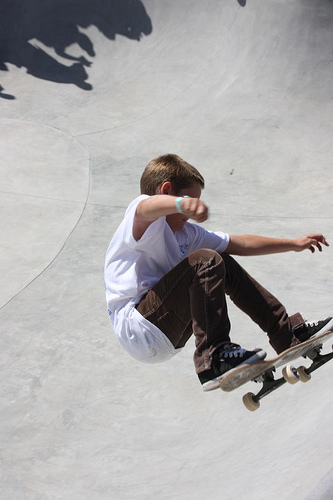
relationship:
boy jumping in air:
[89, 143, 332, 397] [74, 131, 322, 417]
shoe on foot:
[194, 336, 268, 403] [197, 331, 236, 380]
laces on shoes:
[218, 342, 249, 360] [217, 330, 331, 411]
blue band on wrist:
[169, 192, 194, 223] [283, 230, 305, 257]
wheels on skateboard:
[240, 345, 332, 411] [221, 329, 331, 411]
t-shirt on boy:
[101, 203, 198, 319] [94, 139, 244, 315]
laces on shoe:
[218, 342, 249, 360] [188, 341, 268, 394]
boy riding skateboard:
[104, 153, 331, 395] [221, 329, 331, 411]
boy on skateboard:
[104, 153, 331, 395] [195, 319, 331, 413]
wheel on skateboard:
[245, 392, 258, 410] [184, 328, 317, 411]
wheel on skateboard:
[291, 366, 313, 386] [231, 329, 328, 388]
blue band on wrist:
[175, 192, 188, 217] [166, 193, 192, 218]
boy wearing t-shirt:
[104, 153, 331, 395] [98, 193, 228, 365]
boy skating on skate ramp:
[104, 153, 331, 395] [4, 5, 323, 491]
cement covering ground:
[60, 396, 255, 485] [5, 349, 324, 495]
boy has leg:
[104, 153, 331, 395] [131, 248, 265, 392]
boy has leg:
[104, 153, 331, 395] [224, 251, 329, 355]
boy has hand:
[104, 153, 331, 395] [292, 229, 331, 256]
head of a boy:
[131, 146, 211, 224] [75, 113, 299, 495]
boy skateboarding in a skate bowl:
[104, 153, 331, 395] [0, 0, 332, 499]